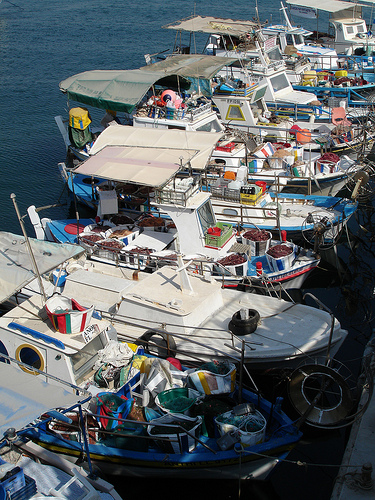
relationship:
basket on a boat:
[157, 384, 209, 423] [55, 107, 357, 250]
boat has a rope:
[55, 107, 357, 250] [245, 448, 368, 473]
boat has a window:
[55, 107, 357, 250] [15, 344, 43, 374]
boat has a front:
[55, 107, 357, 250] [248, 189, 358, 247]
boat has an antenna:
[55, 107, 357, 250] [12, 194, 47, 299]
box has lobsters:
[268, 244, 298, 269] [267, 245, 292, 255]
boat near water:
[55, 107, 357, 250] [2, 1, 374, 495]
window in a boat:
[15, 344, 43, 374] [55, 107, 357, 250]